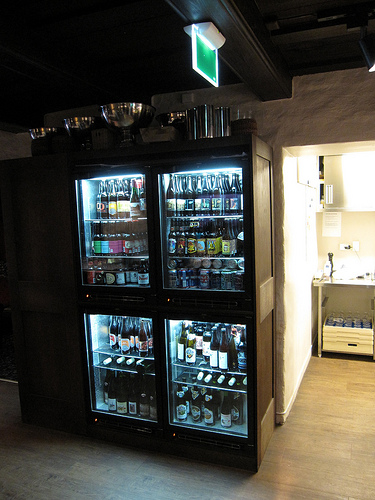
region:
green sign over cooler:
[172, 14, 238, 85]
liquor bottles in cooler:
[97, 165, 250, 440]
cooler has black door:
[80, 181, 262, 456]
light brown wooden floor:
[38, 451, 143, 498]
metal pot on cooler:
[196, 108, 227, 137]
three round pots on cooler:
[32, 94, 156, 143]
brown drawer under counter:
[320, 305, 373, 360]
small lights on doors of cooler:
[73, 293, 243, 336]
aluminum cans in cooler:
[167, 252, 247, 297]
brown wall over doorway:
[285, 87, 365, 145]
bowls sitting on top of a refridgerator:
[18, 114, 275, 149]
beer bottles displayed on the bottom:
[74, 319, 264, 479]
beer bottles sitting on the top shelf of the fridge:
[96, 179, 255, 219]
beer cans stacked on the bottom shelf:
[170, 265, 246, 297]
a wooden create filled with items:
[322, 302, 374, 362]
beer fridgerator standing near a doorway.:
[27, 158, 362, 437]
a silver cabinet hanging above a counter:
[313, 152, 368, 223]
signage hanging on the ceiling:
[173, 41, 249, 90]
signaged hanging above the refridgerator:
[174, 16, 246, 87]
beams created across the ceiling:
[232, 16, 300, 108]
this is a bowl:
[26, 115, 51, 142]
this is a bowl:
[58, 100, 95, 138]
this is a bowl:
[97, 92, 145, 131]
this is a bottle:
[201, 327, 222, 372]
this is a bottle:
[169, 326, 192, 369]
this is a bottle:
[226, 332, 243, 375]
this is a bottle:
[170, 382, 197, 427]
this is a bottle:
[187, 382, 206, 427]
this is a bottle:
[195, 390, 215, 432]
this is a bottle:
[211, 390, 240, 433]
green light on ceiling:
[178, 20, 225, 91]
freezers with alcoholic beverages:
[76, 303, 263, 469]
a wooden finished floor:
[311, 371, 347, 488]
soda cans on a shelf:
[313, 315, 373, 359]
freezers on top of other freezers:
[56, 140, 257, 296]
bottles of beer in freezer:
[79, 182, 138, 216]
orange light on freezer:
[167, 429, 180, 438]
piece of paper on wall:
[321, 209, 345, 242]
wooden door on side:
[226, 286, 279, 471]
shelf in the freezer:
[168, 362, 246, 380]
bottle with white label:
[208, 324, 218, 369]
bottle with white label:
[217, 325, 228, 370]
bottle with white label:
[201, 323, 209, 357]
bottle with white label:
[187, 321, 196, 363]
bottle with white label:
[177, 321, 188, 362]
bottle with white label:
[220, 387, 231, 427]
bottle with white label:
[202, 389, 215, 424]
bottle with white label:
[191, 385, 202, 420]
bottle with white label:
[176, 385, 186, 421]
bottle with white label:
[106, 370, 116, 413]